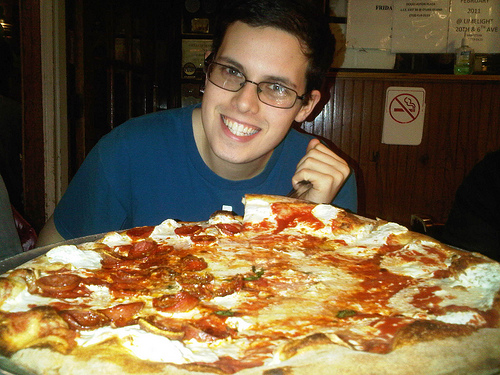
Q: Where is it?
A: This is at the restaurant.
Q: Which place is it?
A: It is a restaurant.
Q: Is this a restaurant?
A: Yes, it is a restaurant.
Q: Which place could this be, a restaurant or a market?
A: It is a restaurant.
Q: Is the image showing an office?
A: No, the picture is showing a restaurant.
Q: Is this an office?
A: No, it is a restaurant.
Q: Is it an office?
A: No, it is a restaurant.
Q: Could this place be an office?
A: No, it is a restaurant.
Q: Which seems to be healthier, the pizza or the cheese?
A: The cheese is healthier than the pizza.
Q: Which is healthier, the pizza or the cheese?
A: The cheese is healthier than the pizza.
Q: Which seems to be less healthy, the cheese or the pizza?
A: The pizza is less healthy than the cheese.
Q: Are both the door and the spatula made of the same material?
A: No, the door is made of wood and the spatula is made of metal.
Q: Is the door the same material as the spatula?
A: No, the door is made of wood and the spatula is made of metal.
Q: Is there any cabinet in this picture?
A: No, there are no cabinets.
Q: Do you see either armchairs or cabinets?
A: No, there are no cabinets or armchairs.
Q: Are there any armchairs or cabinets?
A: No, there are no cabinets or armchairs.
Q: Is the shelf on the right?
A: Yes, the shelf is on the right of the image.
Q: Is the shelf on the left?
A: No, the shelf is on the right of the image.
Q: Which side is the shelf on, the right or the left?
A: The shelf is on the right of the image.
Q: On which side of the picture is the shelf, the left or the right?
A: The shelf is on the right of the image.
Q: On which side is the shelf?
A: The shelf is on the right of the image.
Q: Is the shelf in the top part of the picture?
A: Yes, the shelf is in the top of the image.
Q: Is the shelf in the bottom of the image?
A: No, the shelf is in the top of the image.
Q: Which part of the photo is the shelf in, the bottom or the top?
A: The shelf is in the top of the image.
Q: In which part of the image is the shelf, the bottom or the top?
A: The shelf is in the top of the image.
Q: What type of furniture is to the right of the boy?
A: The piece of furniture is a shelf.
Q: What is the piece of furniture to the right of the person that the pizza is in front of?
A: The piece of furniture is a shelf.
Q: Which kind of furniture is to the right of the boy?
A: The piece of furniture is a shelf.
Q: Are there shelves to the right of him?
A: Yes, there is a shelf to the right of the boy.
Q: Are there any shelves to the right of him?
A: Yes, there is a shelf to the right of the boy.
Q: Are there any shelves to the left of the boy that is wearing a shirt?
A: No, the shelf is to the right of the boy.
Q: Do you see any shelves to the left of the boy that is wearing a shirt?
A: No, the shelf is to the right of the boy.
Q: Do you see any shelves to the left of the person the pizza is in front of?
A: No, the shelf is to the right of the boy.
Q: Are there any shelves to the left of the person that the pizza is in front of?
A: No, the shelf is to the right of the boy.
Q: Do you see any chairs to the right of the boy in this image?
A: No, there is a shelf to the right of the boy.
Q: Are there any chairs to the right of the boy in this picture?
A: No, there is a shelf to the right of the boy.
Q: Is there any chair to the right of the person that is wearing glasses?
A: No, there is a shelf to the right of the boy.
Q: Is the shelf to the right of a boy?
A: Yes, the shelf is to the right of a boy.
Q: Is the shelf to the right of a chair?
A: No, the shelf is to the right of a boy.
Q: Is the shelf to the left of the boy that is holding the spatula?
A: No, the shelf is to the right of the boy.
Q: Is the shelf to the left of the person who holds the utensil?
A: No, the shelf is to the right of the boy.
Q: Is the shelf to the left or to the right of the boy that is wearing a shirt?
A: The shelf is to the right of the boy.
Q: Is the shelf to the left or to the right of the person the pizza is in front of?
A: The shelf is to the right of the boy.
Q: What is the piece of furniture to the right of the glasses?
A: The piece of furniture is a shelf.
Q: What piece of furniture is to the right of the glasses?
A: The piece of furniture is a shelf.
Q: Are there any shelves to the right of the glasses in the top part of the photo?
A: Yes, there is a shelf to the right of the glasses.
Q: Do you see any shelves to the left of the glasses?
A: No, the shelf is to the right of the glasses.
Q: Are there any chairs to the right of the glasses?
A: No, there is a shelf to the right of the glasses.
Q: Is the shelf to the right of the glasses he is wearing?
A: Yes, the shelf is to the right of the glasses.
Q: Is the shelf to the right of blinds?
A: No, the shelf is to the right of the glasses.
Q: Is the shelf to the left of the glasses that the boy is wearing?
A: No, the shelf is to the right of the glasses.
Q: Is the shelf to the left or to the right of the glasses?
A: The shelf is to the right of the glasses.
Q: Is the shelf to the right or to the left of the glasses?
A: The shelf is to the right of the glasses.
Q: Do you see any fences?
A: No, there are no fences.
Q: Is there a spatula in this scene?
A: Yes, there is a spatula.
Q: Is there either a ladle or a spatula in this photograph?
A: Yes, there is a spatula.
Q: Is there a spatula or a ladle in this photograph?
A: Yes, there is a spatula.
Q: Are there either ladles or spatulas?
A: Yes, there is a spatula.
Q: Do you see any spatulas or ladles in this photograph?
A: Yes, there is a spatula.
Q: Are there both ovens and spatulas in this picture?
A: No, there is a spatula but no ovens.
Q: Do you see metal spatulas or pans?
A: Yes, there is a metal spatula.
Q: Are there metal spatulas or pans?
A: Yes, there is a metal spatula.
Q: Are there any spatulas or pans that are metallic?
A: Yes, the spatula is metallic.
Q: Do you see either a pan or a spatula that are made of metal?
A: Yes, the spatula is made of metal.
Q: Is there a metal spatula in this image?
A: Yes, there is a metal spatula.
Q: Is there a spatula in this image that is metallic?
A: Yes, there is a spatula that is metallic.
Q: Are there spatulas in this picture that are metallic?
A: Yes, there is a spatula that is metallic.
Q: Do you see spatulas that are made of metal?
A: Yes, there is a spatula that is made of metal.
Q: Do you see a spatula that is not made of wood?
A: Yes, there is a spatula that is made of metal.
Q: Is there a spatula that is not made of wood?
A: Yes, there is a spatula that is made of metal.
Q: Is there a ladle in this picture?
A: No, there are no ladles.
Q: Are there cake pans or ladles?
A: No, there are no ladles or cake pans.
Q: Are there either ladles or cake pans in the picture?
A: No, there are no ladles or cake pans.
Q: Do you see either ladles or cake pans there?
A: No, there are no ladles or cake pans.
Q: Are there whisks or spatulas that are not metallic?
A: No, there is a spatula but it is metallic.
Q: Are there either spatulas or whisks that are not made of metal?
A: No, there is a spatula but it is made of metal.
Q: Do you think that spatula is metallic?
A: Yes, the spatula is metallic.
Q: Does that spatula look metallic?
A: Yes, the spatula is metallic.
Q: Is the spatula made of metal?
A: Yes, the spatula is made of metal.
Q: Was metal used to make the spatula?
A: Yes, the spatula is made of metal.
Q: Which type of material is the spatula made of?
A: The spatula is made of metal.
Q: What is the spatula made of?
A: The spatula is made of metal.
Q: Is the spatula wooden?
A: No, the spatula is metallic.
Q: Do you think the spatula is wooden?
A: No, the spatula is metallic.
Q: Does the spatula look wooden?
A: No, the spatula is metallic.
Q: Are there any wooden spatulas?
A: No, there is a spatula but it is metallic.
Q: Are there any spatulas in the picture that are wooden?
A: No, there is a spatula but it is metallic.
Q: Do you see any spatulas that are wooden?
A: No, there is a spatula but it is metallic.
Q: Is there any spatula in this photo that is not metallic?
A: No, there is a spatula but it is metallic.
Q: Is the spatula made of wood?
A: No, the spatula is made of metal.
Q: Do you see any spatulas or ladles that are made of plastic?
A: No, there is a spatula but it is made of metal.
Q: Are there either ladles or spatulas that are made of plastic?
A: No, there is a spatula but it is made of metal.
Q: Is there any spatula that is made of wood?
A: No, there is a spatula but it is made of metal.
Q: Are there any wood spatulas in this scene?
A: No, there is a spatula but it is made of metal.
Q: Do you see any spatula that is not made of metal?
A: No, there is a spatula but it is made of metal.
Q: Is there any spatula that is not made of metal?
A: No, there is a spatula but it is made of metal.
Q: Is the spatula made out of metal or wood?
A: The spatula is made of metal.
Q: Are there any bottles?
A: Yes, there is a bottle.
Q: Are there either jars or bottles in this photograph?
A: Yes, there is a bottle.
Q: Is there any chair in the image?
A: No, there are no chairs.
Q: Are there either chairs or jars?
A: No, there are no chairs or jars.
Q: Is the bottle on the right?
A: Yes, the bottle is on the right of the image.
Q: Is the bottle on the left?
A: No, the bottle is on the right of the image.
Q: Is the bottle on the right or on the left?
A: The bottle is on the right of the image.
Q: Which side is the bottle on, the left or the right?
A: The bottle is on the right of the image.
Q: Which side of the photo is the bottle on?
A: The bottle is on the right of the image.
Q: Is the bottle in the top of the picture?
A: Yes, the bottle is in the top of the image.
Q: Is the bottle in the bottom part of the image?
A: No, the bottle is in the top of the image.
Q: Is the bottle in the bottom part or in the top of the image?
A: The bottle is in the top of the image.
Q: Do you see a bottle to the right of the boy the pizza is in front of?
A: Yes, there is a bottle to the right of the boy.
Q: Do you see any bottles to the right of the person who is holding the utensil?
A: Yes, there is a bottle to the right of the boy.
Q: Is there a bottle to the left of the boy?
A: No, the bottle is to the right of the boy.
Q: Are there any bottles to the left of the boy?
A: No, the bottle is to the right of the boy.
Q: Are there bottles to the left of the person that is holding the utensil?
A: No, the bottle is to the right of the boy.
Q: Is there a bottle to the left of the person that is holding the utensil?
A: No, the bottle is to the right of the boy.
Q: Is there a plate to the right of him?
A: No, there is a bottle to the right of the boy.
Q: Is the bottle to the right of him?
A: Yes, the bottle is to the right of the boy.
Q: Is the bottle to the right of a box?
A: No, the bottle is to the right of the boy.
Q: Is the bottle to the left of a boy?
A: No, the bottle is to the right of a boy.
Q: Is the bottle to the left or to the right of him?
A: The bottle is to the right of the boy.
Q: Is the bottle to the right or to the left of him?
A: The bottle is to the right of the boy.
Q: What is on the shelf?
A: The bottle is on the shelf.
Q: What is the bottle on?
A: The bottle is on the shelf.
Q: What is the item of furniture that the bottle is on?
A: The piece of furniture is a shelf.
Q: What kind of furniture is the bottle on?
A: The bottle is on the shelf.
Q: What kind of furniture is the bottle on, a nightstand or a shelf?
A: The bottle is on a shelf.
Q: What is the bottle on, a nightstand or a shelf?
A: The bottle is on a shelf.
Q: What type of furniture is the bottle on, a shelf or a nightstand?
A: The bottle is on a shelf.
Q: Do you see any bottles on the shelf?
A: Yes, there is a bottle on the shelf.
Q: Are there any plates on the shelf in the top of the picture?
A: No, there is a bottle on the shelf.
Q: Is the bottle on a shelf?
A: Yes, the bottle is on a shelf.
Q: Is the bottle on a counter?
A: No, the bottle is on a shelf.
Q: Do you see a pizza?
A: Yes, there is a pizza.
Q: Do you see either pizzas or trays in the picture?
A: Yes, there is a pizza.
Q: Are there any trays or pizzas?
A: Yes, there is a pizza.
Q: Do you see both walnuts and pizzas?
A: No, there is a pizza but no walnuts.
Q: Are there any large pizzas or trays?
A: Yes, there is a large pizza.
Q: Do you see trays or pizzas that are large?
A: Yes, the pizza is large.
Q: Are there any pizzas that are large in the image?
A: Yes, there is a large pizza.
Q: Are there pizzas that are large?
A: Yes, there is a pizza that is large.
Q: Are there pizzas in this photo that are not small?
A: Yes, there is a large pizza.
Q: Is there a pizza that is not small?
A: Yes, there is a large pizza.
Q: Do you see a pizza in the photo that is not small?
A: Yes, there is a large pizza.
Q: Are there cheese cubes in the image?
A: No, there are no cheese cubes.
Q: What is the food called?
A: The food is a pizza.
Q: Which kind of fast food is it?
A: The food is a pizza.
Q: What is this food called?
A: This is a pizza.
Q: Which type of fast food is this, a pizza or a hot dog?
A: This is a pizza.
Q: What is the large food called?
A: The food is a pizza.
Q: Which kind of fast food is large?
A: The fast food is a pizza.